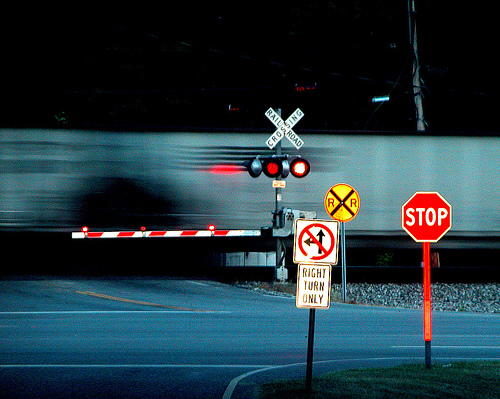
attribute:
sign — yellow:
[326, 181, 372, 224]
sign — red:
[395, 186, 467, 260]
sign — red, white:
[299, 263, 330, 308]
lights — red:
[242, 147, 314, 201]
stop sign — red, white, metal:
[396, 186, 454, 359]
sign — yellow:
[380, 174, 473, 369]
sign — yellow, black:
[386, 157, 473, 257]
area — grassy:
[314, 340, 498, 397]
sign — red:
[397, 189, 452, 240]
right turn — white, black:
[286, 263, 336, 317]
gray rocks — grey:
[438, 287, 498, 316]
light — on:
[234, 153, 319, 185]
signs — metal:
[253, 85, 381, 351]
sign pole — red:
[400, 183, 477, 323]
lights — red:
[76, 222, 216, 232]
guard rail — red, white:
[69, 229, 268, 241]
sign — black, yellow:
[322, 178, 362, 220]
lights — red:
[239, 148, 319, 180]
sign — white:
[261, 105, 305, 152]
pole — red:
[386, 251, 445, 366]